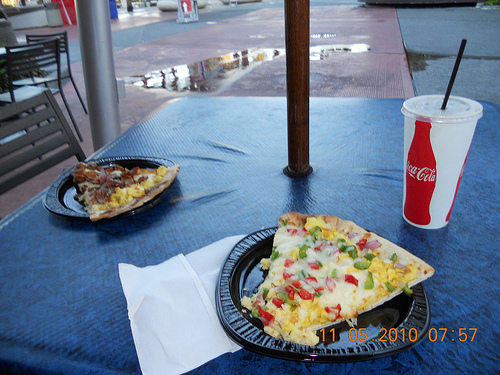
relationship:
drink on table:
[390, 85, 487, 235] [3, 2, 496, 374]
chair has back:
[3, 75, 85, 203] [1, 84, 71, 176]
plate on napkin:
[37, 135, 189, 237] [102, 225, 242, 372]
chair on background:
[3, 75, 85, 203] [1, 14, 74, 94]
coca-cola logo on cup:
[403, 119, 435, 225] [399, 96, 484, 230]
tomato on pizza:
[296, 286, 310, 298] [235, 210, 437, 350]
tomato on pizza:
[268, 277, 305, 305] [229, 200, 439, 350]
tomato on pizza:
[260, 301, 282, 332] [229, 200, 439, 350]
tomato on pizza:
[289, 271, 305, 298] [218, 196, 450, 361]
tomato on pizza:
[313, 277, 330, 296] [246, 200, 419, 373]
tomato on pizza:
[312, 241, 324, 258] [253, 215, 430, 347]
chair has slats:
[3, 75, 85, 203] [6, 73, 103, 204]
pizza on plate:
[65, 160, 182, 221] [44, 157, 176, 219]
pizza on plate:
[256, 208, 436, 335] [214, 229, 430, 356]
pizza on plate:
[65, 160, 182, 221] [41, 152, 181, 219]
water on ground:
[110, 24, 375, 124] [124, 16, 382, 107]